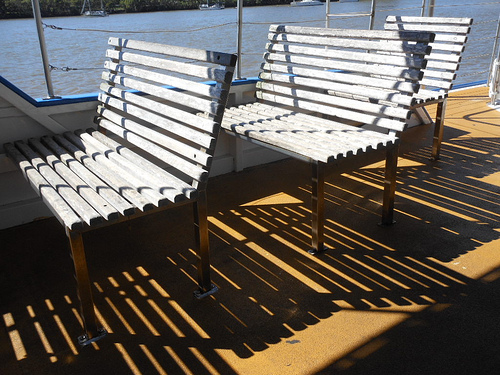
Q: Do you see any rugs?
A: No, there are no rugs.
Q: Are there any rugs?
A: No, there are no rugs.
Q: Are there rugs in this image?
A: No, there are no rugs.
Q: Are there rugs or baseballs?
A: No, there are no rugs or baseballs.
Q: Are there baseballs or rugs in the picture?
A: No, there are no rugs or baseballs.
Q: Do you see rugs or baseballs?
A: No, there are no rugs or baseballs.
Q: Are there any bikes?
A: No, there are no bikes.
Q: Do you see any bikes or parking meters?
A: No, there are no bikes or parking meters.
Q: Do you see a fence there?
A: No, there are no fences.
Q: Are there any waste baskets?
A: No, there are no waste baskets.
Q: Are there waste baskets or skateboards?
A: No, there are no waste baskets or skateboards.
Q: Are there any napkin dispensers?
A: No, there are no napkin dispensers.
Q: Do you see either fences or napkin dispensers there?
A: No, there are no napkin dispensers or fences.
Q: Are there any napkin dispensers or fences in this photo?
A: No, there are no napkin dispensers or fences.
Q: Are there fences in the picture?
A: No, there are no fences.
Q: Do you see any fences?
A: No, there are no fences.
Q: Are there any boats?
A: Yes, there is a boat.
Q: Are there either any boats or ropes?
A: Yes, there is a boat.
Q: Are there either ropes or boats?
A: Yes, there is a boat.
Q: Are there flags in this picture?
A: No, there are no flags.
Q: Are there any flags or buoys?
A: No, there are no flags or buoys.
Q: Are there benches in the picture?
A: Yes, there is a bench.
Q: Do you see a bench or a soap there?
A: Yes, there is a bench.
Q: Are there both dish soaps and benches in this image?
A: No, there is a bench but no dish soaps.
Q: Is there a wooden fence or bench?
A: Yes, there is a wood bench.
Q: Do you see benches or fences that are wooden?
A: Yes, the bench is wooden.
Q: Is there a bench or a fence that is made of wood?
A: Yes, the bench is made of wood.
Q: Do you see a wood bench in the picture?
A: Yes, there is a wood bench.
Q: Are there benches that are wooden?
A: Yes, there is a bench that is wooden.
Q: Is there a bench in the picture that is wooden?
A: Yes, there is a bench that is wooden.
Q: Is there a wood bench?
A: Yes, there is a bench that is made of wood.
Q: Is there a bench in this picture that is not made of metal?
A: Yes, there is a bench that is made of wood.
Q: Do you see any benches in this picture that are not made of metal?
A: Yes, there is a bench that is made of wood.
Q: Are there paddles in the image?
A: No, there are no paddles.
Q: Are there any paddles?
A: No, there are no paddles.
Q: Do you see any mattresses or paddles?
A: No, there are no paddles or mattresses.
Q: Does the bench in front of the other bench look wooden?
A: Yes, the bench is wooden.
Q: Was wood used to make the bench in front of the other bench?
A: Yes, the bench is made of wood.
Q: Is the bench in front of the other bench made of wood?
A: Yes, the bench is made of wood.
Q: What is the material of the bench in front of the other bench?
A: The bench is made of wood.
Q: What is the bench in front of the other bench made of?
A: The bench is made of wood.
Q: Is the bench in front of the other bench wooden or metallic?
A: The bench is wooden.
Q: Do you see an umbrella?
A: No, there are no umbrellas.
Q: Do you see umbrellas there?
A: No, there are no umbrellas.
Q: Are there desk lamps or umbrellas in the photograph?
A: No, there are no umbrellas or desk lamps.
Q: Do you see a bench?
A: Yes, there is a bench.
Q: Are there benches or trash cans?
A: Yes, there is a bench.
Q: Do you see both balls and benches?
A: No, there is a bench but no balls.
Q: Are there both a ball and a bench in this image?
A: No, there is a bench but no balls.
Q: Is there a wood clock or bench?
A: Yes, there is a wood bench.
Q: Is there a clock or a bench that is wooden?
A: Yes, the bench is wooden.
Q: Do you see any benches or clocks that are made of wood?
A: Yes, the bench is made of wood.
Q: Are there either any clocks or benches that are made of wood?
A: Yes, the bench is made of wood.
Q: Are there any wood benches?
A: Yes, there is a wood bench.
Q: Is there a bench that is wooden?
A: Yes, there is a bench that is wooden.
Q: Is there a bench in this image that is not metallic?
A: Yes, there is a wooden bench.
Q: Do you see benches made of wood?
A: Yes, there is a bench that is made of wood.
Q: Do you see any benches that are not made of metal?
A: Yes, there is a bench that is made of wood.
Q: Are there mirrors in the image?
A: No, there are no mirrors.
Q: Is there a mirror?
A: No, there are no mirrors.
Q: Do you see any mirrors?
A: No, there are no mirrors.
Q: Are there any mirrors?
A: No, there are no mirrors.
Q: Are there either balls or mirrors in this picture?
A: No, there are no mirrors or balls.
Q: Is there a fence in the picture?
A: No, there are no fences.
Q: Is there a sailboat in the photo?
A: Yes, there is a sailboat.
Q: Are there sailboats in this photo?
A: Yes, there is a sailboat.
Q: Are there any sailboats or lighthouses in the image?
A: Yes, there is a sailboat.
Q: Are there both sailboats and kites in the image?
A: No, there is a sailboat but no kites.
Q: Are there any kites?
A: No, there are no kites.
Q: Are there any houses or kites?
A: No, there are no kites or houses.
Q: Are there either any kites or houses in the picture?
A: No, there are no kites or houses.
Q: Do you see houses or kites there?
A: No, there are no kites or houses.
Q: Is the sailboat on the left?
A: Yes, the sailboat is on the left of the image.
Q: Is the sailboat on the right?
A: No, the sailboat is on the left of the image.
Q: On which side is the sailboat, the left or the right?
A: The sailboat is on the left of the image.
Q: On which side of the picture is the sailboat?
A: The sailboat is on the left of the image.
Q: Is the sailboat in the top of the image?
A: Yes, the sailboat is in the top of the image.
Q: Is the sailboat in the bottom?
A: No, the sailboat is in the top of the image.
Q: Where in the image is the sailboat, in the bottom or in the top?
A: The sailboat is in the top of the image.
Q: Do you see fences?
A: No, there are no fences.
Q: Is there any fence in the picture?
A: No, there are no fences.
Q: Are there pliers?
A: No, there are no pliers.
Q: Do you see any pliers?
A: No, there are no pliers.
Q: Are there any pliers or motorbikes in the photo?
A: No, there are no pliers or motorbikes.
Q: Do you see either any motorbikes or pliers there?
A: No, there are no pliers or motorbikes.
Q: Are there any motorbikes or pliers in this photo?
A: No, there are no pliers or motorbikes.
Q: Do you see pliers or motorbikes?
A: No, there are no pliers or motorbikes.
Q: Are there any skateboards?
A: No, there are no skateboards.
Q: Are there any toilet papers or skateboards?
A: No, there are no skateboards or toilet papers.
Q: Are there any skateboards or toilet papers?
A: No, there are no skateboards or toilet papers.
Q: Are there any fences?
A: No, there are no fences.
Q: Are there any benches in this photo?
A: Yes, there is a bench.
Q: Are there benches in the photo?
A: Yes, there is a bench.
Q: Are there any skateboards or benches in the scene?
A: Yes, there is a bench.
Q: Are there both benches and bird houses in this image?
A: No, there is a bench but no bird houses.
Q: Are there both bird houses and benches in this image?
A: No, there is a bench but no bird houses.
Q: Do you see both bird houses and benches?
A: No, there is a bench but no bird houses.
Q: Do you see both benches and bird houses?
A: No, there is a bench but no bird houses.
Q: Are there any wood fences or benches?
A: Yes, there is a wood bench.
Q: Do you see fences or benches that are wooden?
A: Yes, the bench is wooden.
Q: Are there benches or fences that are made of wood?
A: Yes, the bench is made of wood.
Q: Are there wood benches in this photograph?
A: Yes, there is a bench that is made of wood.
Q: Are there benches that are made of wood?
A: Yes, there is a bench that is made of wood.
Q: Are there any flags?
A: No, there are no flags.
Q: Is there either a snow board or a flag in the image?
A: No, there are no flags or snowboards.